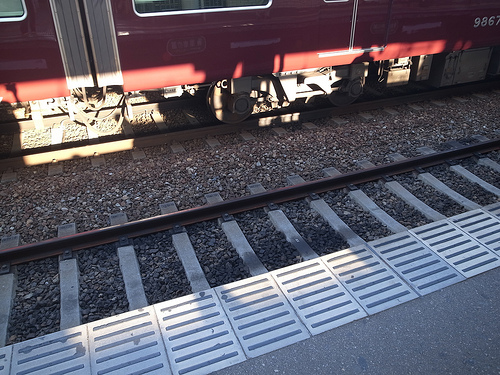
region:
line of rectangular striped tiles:
[20, 202, 496, 364]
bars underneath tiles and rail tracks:
[20, 140, 471, 355]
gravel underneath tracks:
[66, 155, 431, 295]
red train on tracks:
[40, 16, 430, 157]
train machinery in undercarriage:
[200, 57, 420, 124]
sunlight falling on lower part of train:
[20, 35, 432, 155]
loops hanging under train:
[60, 70, 141, 140]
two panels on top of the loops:
[50, 1, 125, 91]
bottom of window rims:
[0, 0, 280, 30]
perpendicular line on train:
[306, 15, 387, 67]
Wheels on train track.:
[152, 83, 417, 145]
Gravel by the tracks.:
[147, 199, 266, 329]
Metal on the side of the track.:
[184, 282, 330, 368]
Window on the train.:
[128, 2, 265, 46]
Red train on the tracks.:
[52, 2, 492, 171]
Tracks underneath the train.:
[19, 116, 189, 185]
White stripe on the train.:
[338, 2, 390, 64]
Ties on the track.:
[165, 188, 274, 314]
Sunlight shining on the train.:
[22, 95, 187, 167]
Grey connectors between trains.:
[47, 2, 145, 105]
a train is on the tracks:
[15, 1, 497, 152]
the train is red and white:
[5, 1, 496, 132]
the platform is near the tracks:
[2, 203, 497, 365]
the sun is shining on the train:
[2, 21, 497, 156]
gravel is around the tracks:
[2, 78, 497, 330]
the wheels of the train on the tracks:
[200, 63, 366, 129]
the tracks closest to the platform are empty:
[5, 140, 491, 330]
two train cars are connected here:
[7, 1, 152, 129]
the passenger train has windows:
[5, 0, 271, 21]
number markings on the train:
[466, 10, 498, 39]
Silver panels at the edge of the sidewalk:
[3, 197, 499, 373]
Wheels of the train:
[195, 62, 367, 123]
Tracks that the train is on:
[2, 74, 499, 181]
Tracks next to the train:
[5, 135, 498, 283]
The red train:
[2, 0, 499, 109]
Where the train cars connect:
[45, 2, 125, 118]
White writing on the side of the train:
[470, 11, 499, 28]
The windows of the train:
[0, 0, 290, 25]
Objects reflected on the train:
[0, 22, 445, 76]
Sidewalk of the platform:
[188, 261, 498, 373]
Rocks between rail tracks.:
[74, 254, 207, 354]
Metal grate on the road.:
[207, 267, 398, 359]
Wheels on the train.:
[187, 36, 457, 128]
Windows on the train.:
[120, 0, 329, 30]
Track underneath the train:
[195, 83, 397, 180]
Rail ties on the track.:
[180, 155, 460, 260]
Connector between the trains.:
[42, 0, 134, 105]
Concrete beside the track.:
[302, 305, 394, 365]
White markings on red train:
[140, 14, 399, 90]